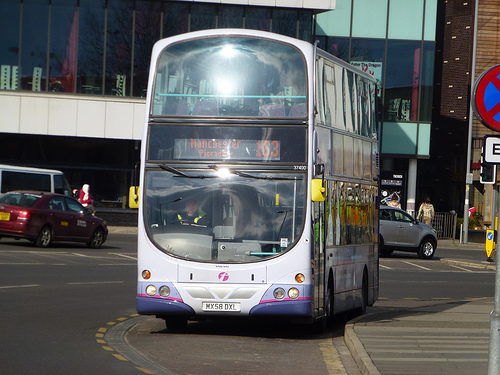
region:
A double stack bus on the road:
[137, 27, 380, 331]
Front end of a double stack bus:
[134, 30, 344, 332]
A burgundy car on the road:
[0, 186, 112, 249]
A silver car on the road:
[379, 203, 440, 258]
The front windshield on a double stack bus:
[142, 32, 309, 265]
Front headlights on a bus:
[146, 283, 299, 300]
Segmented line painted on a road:
[91, 316, 146, 372]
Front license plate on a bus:
[200, 300, 245, 312]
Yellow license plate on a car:
[2, 210, 12, 217]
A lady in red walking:
[76, 183, 92, 210]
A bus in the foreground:
[119, 14, 412, 346]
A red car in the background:
[2, 181, 115, 266]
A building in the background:
[1, 2, 499, 235]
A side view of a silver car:
[381, 193, 442, 265]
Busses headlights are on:
[130, 256, 305, 316]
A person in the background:
[404, 188, 444, 238]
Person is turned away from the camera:
[408, 190, 443, 235]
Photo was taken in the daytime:
[5, 2, 499, 367]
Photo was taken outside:
[5, 1, 499, 363]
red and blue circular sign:
[468, 61, 499, 129]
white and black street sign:
[480, 133, 499, 167]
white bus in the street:
[135, 27, 382, 335]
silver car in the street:
[376, 199, 439, 259]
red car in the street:
[1, 188, 111, 248]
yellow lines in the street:
[93, 311, 158, 373]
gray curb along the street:
[341, 308, 386, 373]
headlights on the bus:
[143, 283, 300, 300]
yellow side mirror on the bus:
[309, 173, 327, 203]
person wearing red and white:
[76, 180, 95, 210]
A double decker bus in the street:
[132, 23, 391, 341]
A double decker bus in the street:
[126, 24, 390, 344]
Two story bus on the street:
[136, 28, 380, 320]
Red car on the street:
[0, 190, 121, 250]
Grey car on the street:
[376, 202, 436, 258]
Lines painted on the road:
[32, 246, 129, 288]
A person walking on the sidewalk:
[418, 195, 445, 240]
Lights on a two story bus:
[138, 268, 310, 301]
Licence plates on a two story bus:
[196, 298, 246, 313]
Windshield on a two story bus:
[146, 158, 306, 264]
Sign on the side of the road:
[476, 60, 499, 174]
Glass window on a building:
[1, 8, 136, 108]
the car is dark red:
[0, 191, 108, 246]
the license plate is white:
[201, 301, 240, 312]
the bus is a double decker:
[137, 28, 381, 330]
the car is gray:
[376, 205, 437, 257]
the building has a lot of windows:
[0, 0, 441, 220]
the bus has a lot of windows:
[135, 27, 380, 329]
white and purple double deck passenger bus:
[123, 25, 373, 354]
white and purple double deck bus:
[115, 25, 393, 334]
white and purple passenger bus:
[116, 10, 390, 327]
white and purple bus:
[119, 6, 389, 338]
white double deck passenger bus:
[136, 29, 390, 326]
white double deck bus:
[132, 16, 392, 331]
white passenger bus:
[131, 28, 396, 340]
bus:
[138, 25, 374, 346]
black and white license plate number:
[199, 300, 246, 316]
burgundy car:
[6, 180, 110, 253]